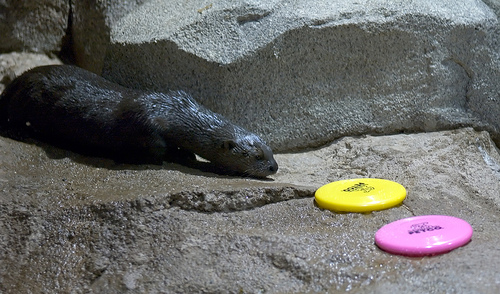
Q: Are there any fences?
A: No, there are no fences.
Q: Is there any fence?
A: No, there are no fences.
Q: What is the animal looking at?
A: The animal is looking at the frisbee.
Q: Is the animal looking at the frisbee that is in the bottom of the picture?
A: Yes, the animal is looking at the frisbee.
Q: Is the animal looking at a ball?
A: No, the animal is looking at the frisbee.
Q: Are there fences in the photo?
A: No, there are no fences.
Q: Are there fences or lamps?
A: No, there are no fences or lamps.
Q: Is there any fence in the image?
A: No, there are no fences.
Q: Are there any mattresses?
A: No, there are no mattresses.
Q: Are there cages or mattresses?
A: No, there are no mattresses or cages.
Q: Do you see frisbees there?
A: Yes, there is a frisbee.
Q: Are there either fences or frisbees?
A: Yes, there is a frisbee.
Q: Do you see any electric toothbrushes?
A: No, there are no electric toothbrushes.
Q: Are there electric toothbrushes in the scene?
A: No, there are no electric toothbrushes.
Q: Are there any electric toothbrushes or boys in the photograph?
A: No, there are no electric toothbrushes or boys.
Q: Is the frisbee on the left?
A: No, the frisbee is on the right of the image.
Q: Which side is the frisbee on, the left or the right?
A: The frisbee is on the right of the image.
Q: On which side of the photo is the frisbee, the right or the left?
A: The frisbee is on the right of the image.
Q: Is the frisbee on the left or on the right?
A: The frisbee is on the right of the image.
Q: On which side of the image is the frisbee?
A: The frisbee is on the right of the image.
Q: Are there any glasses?
A: No, there are no glasses.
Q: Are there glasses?
A: No, there are no glasses.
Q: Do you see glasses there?
A: No, there are no glasses.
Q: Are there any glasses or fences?
A: No, there are no glasses or fences.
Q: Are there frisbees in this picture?
A: Yes, there is a frisbee.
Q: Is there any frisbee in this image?
A: Yes, there is a frisbee.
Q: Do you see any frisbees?
A: Yes, there is a frisbee.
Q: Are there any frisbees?
A: Yes, there is a frisbee.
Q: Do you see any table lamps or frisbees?
A: Yes, there is a frisbee.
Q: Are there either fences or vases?
A: No, there are no fences or vases.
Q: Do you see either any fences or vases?
A: No, there are no fences or vases.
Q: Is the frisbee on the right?
A: Yes, the frisbee is on the right of the image.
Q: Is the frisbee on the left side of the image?
A: No, the frisbee is on the right of the image.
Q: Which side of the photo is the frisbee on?
A: The frisbee is on the right of the image.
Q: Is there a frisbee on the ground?
A: Yes, there is a frisbee on the ground.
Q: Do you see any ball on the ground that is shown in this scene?
A: No, there is a frisbee on the ground.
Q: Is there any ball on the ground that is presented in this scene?
A: No, there is a frisbee on the ground.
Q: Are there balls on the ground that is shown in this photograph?
A: No, there is a frisbee on the ground.